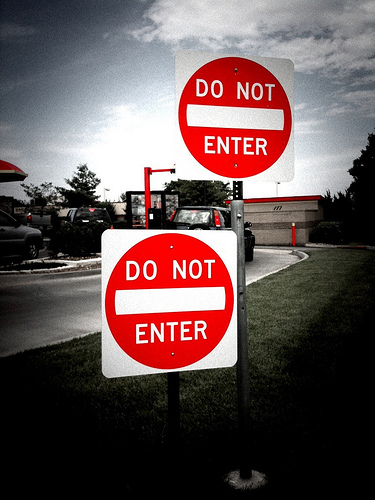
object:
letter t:
[264, 83, 276, 102]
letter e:
[203, 134, 215, 156]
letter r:
[255, 137, 269, 162]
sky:
[0, 2, 374, 210]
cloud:
[122, 0, 374, 88]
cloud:
[290, 103, 307, 113]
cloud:
[101, 33, 111, 43]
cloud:
[0, 25, 38, 38]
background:
[0, 0, 374, 499]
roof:
[0, 160, 28, 182]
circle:
[104, 232, 234, 369]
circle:
[177, 56, 292, 179]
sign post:
[164, 371, 181, 499]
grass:
[0, 244, 374, 499]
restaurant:
[0, 160, 29, 219]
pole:
[290, 222, 297, 248]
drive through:
[0, 208, 45, 266]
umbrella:
[0, 160, 28, 185]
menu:
[128, 190, 164, 222]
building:
[241, 194, 325, 246]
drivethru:
[166, 203, 257, 269]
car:
[154, 203, 255, 262]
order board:
[162, 191, 179, 224]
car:
[42, 205, 113, 257]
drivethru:
[50, 204, 133, 253]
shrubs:
[308, 188, 374, 244]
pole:
[143, 166, 152, 228]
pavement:
[0, 268, 101, 359]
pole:
[229, 174, 251, 479]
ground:
[0, 244, 374, 500]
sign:
[174, 50, 295, 183]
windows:
[171, 204, 209, 226]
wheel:
[24, 243, 40, 259]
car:
[0, 210, 44, 264]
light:
[169, 170, 176, 176]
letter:
[194, 76, 209, 100]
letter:
[123, 259, 139, 283]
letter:
[141, 260, 157, 281]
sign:
[101, 228, 238, 380]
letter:
[170, 258, 185, 282]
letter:
[188, 259, 203, 283]